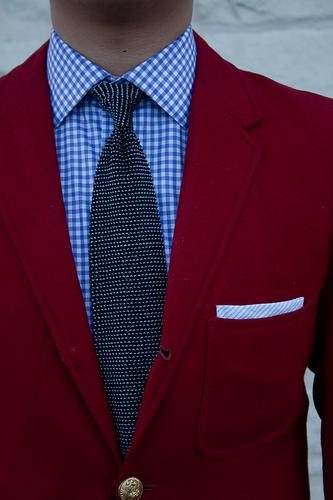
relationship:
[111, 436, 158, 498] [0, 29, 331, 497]
button has jacket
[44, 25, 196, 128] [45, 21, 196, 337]
collar of shirt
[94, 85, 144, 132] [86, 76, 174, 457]
knot at top of tie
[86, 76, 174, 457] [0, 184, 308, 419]
tie hanging on torso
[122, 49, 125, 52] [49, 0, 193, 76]
freckle on neck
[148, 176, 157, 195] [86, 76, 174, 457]
edge on tie